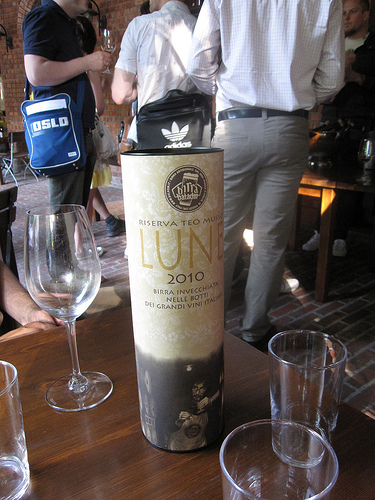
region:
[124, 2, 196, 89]
A white shirt in the photo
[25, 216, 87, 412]
A wine glass in the photo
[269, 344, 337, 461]
A glass in the photo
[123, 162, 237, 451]
A can on the table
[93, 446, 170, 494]
Wooden table in the picture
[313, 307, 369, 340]
Tiles in the photo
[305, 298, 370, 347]
Tiled floor in the picture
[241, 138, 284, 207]
A gray trouser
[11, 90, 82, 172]
A blue bag in the photo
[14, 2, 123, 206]
A man holding a wine bottle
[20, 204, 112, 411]
the glass is empty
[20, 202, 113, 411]
the glass is for wine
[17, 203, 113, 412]
the glass is transparent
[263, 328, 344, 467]
a glass in on the table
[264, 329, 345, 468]
the glass is empty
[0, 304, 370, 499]
the table is made of wood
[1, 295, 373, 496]
the wood is brown in color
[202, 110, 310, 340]
the man is wearing grey pants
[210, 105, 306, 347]
the pants are grey in color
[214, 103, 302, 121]
the man is wearing a belt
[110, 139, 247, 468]
This container should hold a bottle of wine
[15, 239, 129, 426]
This is a wine glass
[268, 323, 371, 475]
This is a water glass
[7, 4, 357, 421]
This appears to be a wine tasting event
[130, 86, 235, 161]
This is an Adiadas shoulder bag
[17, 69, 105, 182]
This is an oslo shoulder bag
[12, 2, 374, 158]
Four men are standing together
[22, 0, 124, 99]
This man is waiting for his wine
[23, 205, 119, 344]
This glass is full of water spots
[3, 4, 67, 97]
The walls are made of bricks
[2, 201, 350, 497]
Glasses on a table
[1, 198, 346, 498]
Empty glasses on a table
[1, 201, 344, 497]
Glasses on a brown table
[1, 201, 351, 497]
Empty glasses on a brown table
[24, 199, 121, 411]
Wine glass on a table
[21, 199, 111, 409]
Wine glass on a brown table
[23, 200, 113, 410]
Empty wine glass on a table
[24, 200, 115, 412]
Empty wine glass on a brown table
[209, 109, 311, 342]
Man is wearing pants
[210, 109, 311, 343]
Man is wearing gray pants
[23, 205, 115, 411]
Wine glass on wooden table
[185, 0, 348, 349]
Person wearing gray pants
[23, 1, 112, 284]
Man with blue bag holding wine glass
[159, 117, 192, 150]
Adidas logo on black bag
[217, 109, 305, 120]
Black belt on gray pants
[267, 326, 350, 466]
Tumbler next to wine box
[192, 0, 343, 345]
Person wearing white checkered button down shirt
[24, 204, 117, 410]
Wine glass is empty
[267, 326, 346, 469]
Glass tumbler is empty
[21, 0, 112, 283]
Man wearing blue polo shirt